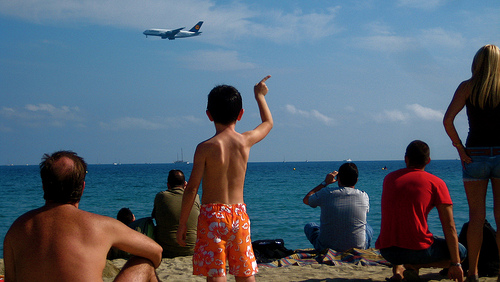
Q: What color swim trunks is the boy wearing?
A: Orange.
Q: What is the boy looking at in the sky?
A: An airplane.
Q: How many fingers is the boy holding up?
A: One.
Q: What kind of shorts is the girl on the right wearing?
A: Blue jean.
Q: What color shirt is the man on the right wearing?
A: Red.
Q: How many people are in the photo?
A: Seven.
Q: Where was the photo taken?
A: A beach.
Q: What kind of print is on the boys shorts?
A: Flower.